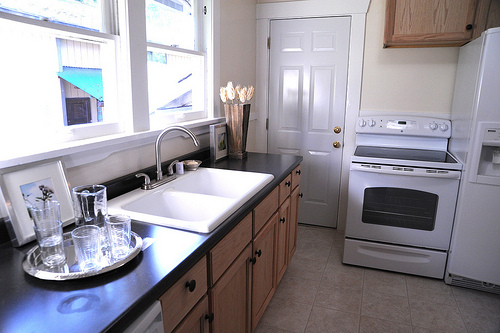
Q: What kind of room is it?
A: A kitchen.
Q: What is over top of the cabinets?
A: A sink.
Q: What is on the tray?
A: Cups.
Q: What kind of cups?
A: Glass cups.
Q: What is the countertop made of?
A: Black granite.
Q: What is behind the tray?
A: A photo.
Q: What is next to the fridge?
A: A stove.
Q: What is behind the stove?
A: A wall.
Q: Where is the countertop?
A: In kitchen.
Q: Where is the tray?
A: On counter.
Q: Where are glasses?
A: On tray.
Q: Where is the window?
A: Over sink.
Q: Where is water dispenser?
A: On fridge.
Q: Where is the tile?
A: On floor.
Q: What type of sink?
A: Kitchen.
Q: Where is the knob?
A: On door.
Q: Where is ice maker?
A: On fridge.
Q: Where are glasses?
A: On tray.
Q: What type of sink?
A: Double.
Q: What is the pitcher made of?
A: Glass.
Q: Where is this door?
A: In the kitchen.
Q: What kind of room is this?
A: Kitchen.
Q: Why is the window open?
A: To let light in.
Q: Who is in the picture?
A: No one.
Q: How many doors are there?
A: One.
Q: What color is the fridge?
A: White.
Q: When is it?
A: Day time.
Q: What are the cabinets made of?
A: Wood.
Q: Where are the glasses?
A: On the tray.